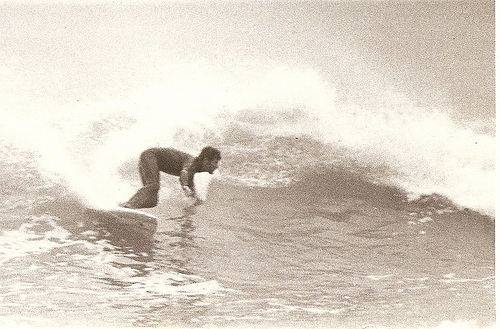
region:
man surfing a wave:
[123, 134, 225, 209]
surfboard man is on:
[100, 198, 162, 230]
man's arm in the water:
[176, 171, 213, 210]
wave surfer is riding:
[14, 55, 494, 231]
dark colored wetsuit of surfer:
[117, 139, 200, 201]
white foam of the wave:
[4, 55, 491, 210]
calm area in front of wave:
[0, 235, 499, 325]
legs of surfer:
[120, 173, 172, 206]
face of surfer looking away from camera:
[195, 143, 225, 178]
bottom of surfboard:
[108, 212, 158, 239]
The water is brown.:
[214, 190, 489, 317]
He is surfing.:
[73, 128, 232, 235]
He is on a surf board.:
[78, 128, 215, 248]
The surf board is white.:
[84, 198, 179, 238]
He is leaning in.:
[106, 121, 218, 246]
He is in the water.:
[118, 133, 229, 240]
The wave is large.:
[12, 2, 485, 271]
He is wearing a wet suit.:
[104, 138, 234, 249]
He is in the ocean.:
[10, 15, 495, 320]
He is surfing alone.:
[2, 13, 489, 318]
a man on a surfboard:
[122, 143, 226, 221]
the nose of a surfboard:
[102, 206, 162, 237]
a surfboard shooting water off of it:
[16, 126, 106, 203]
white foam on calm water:
[5, 220, 217, 327]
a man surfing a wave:
[102, 145, 227, 225]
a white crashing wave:
[232, 67, 498, 227]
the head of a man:
[198, 145, 220, 172]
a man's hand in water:
[186, 188, 203, 205]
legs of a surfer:
[122, 149, 162, 208]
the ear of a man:
[202, 156, 209, 166]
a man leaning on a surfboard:
[122, 143, 224, 222]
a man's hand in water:
[175, 173, 215, 206]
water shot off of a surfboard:
[10, 117, 103, 201]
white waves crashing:
[231, 86, 498, 268]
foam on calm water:
[2, 218, 219, 325]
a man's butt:
[138, 150, 155, 167]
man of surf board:
[75, 119, 231, 244]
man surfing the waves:
[73, 125, 241, 242]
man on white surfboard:
[74, 127, 233, 257]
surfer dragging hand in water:
[61, 129, 236, 261]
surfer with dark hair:
[58, 123, 238, 254]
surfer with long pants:
[56, 118, 255, 243]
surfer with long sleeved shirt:
[84, 128, 236, 254]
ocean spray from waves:
[251, 35, 463, 185]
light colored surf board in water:
[71, 197, 181, 239]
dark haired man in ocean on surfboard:
[80, 123, 262, 240]